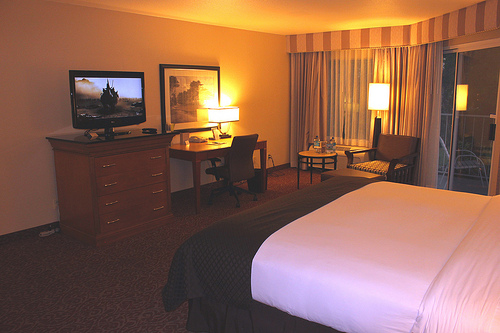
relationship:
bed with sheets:
[141, 163, 491, 329] [246, 181, 498, 331]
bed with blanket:
[141, 163, 491, 329] [168, 174, 362, 324]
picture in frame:
[161, 64, 222, 135] [152, 59, 233, 135]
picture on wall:
[161, 64, 222, 135] [4, 1, 285, 248]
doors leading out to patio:
[426, 48, 498, 180] [433, 124, 498, 200]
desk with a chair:
[173, 132, 269, 215] [210, 134, 262, 215]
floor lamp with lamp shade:
[367, 83, 390, 161] [366, 79, 389, 115]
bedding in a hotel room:
[248, 181, 498, 330] [6, 8, 498, 322]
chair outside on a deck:
[436, 136, 490, 188] [432, 92, 499, 197]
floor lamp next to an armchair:
[359, 83, 391, 161] [348, 124, 417, 187]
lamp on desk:
[209, 109, 242, 140] [166, 125, 267, 208]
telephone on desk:
[172, 126, 215, 150] [162, 118, 266, 205]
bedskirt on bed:
[155, 165, 388, 326] [141, 163, 491, 329]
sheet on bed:
[252, 180, 498, 331] [141, 163, 491, 329]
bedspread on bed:
[147, 166, 396, 330] [141, 163, 491, 329]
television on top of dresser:
[70, 68, 146, 135] [38, 111, 195, 251]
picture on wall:
[161, 64, 222, 135] [6, 23, 306, 228]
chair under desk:
[200, 126, 267, 216] [162, 120, 259, 209]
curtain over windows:
[288, 41, 438, 181] [278, 34, 493, 192]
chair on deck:
[432, 129, 490, 184] [312, 142, 498, 196]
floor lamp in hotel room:
[367, 83, 390, 161] [6, 8, 498, 322]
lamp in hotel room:
[209, 109, 242, 140] [6, 8, 498, 322]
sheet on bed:
[159, 173, 373, 313] [163, 173, 499, 332]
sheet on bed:
[252, 180, 498, 331] [163, 173, 499, 332]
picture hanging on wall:
[157, 59, 222, 136] [4, 1, 285, 248]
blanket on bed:
[250, 179, 499, 331] [163, 173, 499, 332]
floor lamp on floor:
[367, 83, 390, 161] [0, 165, 323, 332]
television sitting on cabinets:
[66, 64, 148, 138] [44, 129, 182, 250]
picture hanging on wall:
[161, 64, 222, 135] [4, 1, 285, 248]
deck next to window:
[298, 151, 338, 188] [285, 35, 499, 194]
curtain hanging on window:
[287, 42, 442, 189] [285, 3, 499, 193]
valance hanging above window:
[288, 0, 499, 52] [285, 3, 499, 193]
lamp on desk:
[209, 109, 242, 140] [172, 135, 270, 215]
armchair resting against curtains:
[344, 117, 419, 183] [289, 42, 442, 189]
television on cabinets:
[66, 64, 148, 138] [44, 129, 182, 250]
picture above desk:
[157, 59, 222, 136] [173, 132, 269, 215]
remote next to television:
[138, 125, 158, 135] [66, 64, 148, 138]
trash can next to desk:
[244, 165, 269, 194] [173, 132, 269, 215]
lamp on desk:
[204, 102, 242, 139] [173, 132, 269, 215]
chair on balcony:
[436, 136, 490, 188] [440, 112, 490, 192]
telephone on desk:
[189, 136, 207, 143] [169, 137, 268, 216]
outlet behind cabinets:
[50, 196, 59, 216] [44, 129, 182, 250]